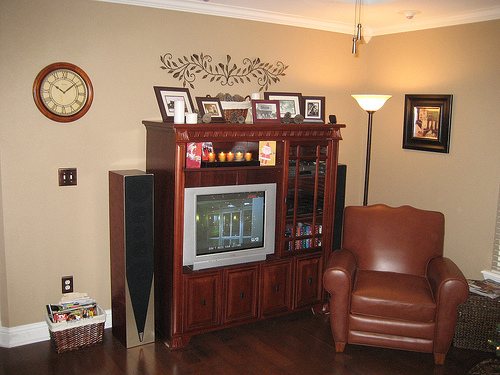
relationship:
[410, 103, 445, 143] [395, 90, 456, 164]
picture in frame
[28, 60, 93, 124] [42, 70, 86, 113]
frame with face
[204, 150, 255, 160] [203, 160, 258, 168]
candles on tray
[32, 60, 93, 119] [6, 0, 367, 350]
clock on wall